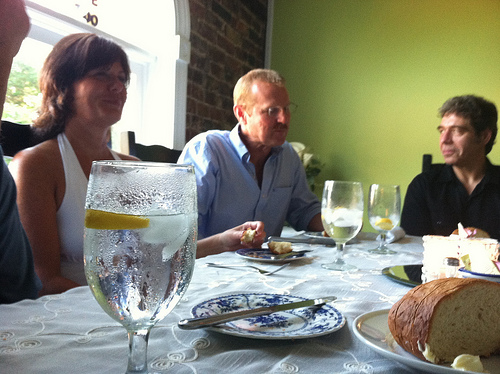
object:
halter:
[124, 326, 149, 373]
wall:
[184, 1, 267, 143]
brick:
[207, 58, 226, 80]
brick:
[188, 83, 205, 100]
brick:
[197, 102, 212, 119]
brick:
[216, 31, 238, 56]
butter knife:
[174, 294, 340, 330]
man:
[178, 69, 329, 237]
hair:
[231, 67, 284, 103]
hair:
[436, 93, 500, 156]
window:
[0, 36, 145, 156]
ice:
[143, 211, 188, 245]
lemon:
[84, 205, 148, 230]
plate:
[190, 291, 346, 340]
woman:
[9, 32, 267, 300]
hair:
[28, 34, 133, 142]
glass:
[81, 160, 199, 373]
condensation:
[85, 165, 200, 327]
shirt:
[177, 121, 321, 240]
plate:
[351, 306, 499, 372]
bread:
[386, 277, 500, 363]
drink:
[320, 208, 363, 241]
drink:
[367, 212, 401, 232]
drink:
[84, 208, 196, 330]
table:
[0, 226, 498, 372]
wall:
[270, 1, 500, 234]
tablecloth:
[1, 231, 429, 374]